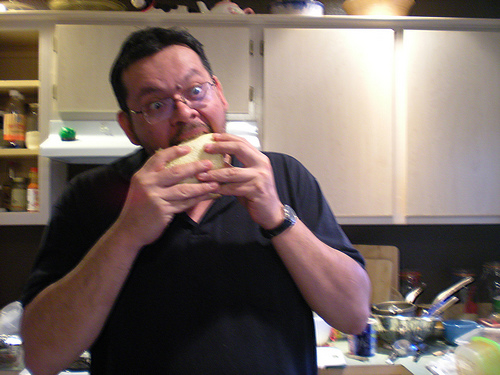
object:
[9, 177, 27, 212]
bottle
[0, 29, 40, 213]
cupboard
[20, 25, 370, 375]
guy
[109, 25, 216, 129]
black hair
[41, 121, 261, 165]
exhaust fan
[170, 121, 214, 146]
mustache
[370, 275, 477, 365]
dishes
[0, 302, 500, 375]
counter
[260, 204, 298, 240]
watch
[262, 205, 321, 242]
wrist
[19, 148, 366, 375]
shirt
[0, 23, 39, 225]
cabinet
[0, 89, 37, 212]
seasoning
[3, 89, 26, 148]
bottle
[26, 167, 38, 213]
bottle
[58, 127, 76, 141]
ball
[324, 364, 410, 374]
boards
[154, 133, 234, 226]
sandwhich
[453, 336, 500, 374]
container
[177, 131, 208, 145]
mouth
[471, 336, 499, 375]
lid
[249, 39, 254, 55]
screws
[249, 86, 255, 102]
screws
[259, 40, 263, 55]
screws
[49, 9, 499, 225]
cabinets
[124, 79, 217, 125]
glasses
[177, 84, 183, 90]
mole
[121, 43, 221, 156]
face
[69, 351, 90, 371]
stove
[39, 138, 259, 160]
overhang